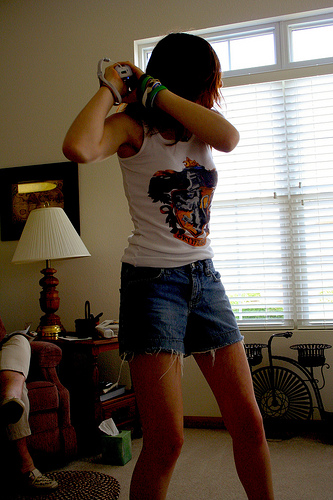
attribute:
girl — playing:
[123, 34, 267, 500]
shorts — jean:
[113, 258, 245, 353]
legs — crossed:
[1, 328, 59, 494]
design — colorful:
[154, 160, 212, 242]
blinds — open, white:
[237, 96, 332, 323]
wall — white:
[10, 22, 79, 108]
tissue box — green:
[102, 418, 132, 465]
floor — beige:
[105, 462, 332, 500]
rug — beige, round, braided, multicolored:
[26, 471, 118, 500]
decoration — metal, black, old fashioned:
[249, 337, 332, 439]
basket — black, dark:
[77, 301, 97, 335]